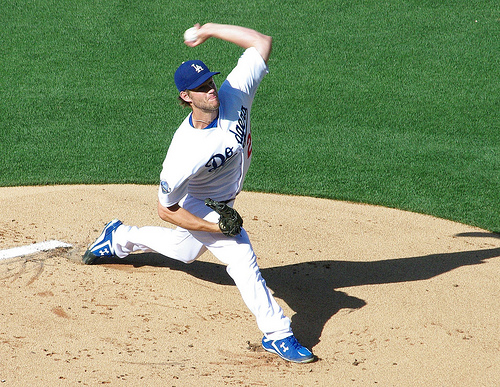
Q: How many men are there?
A: One.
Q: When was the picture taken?
A: Daytime.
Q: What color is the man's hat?
A: Blue.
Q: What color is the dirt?
A: Brown.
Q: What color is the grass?
A: Green.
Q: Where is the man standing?
A: On the dirt.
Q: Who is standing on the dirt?
A: The man.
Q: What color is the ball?
A: White.